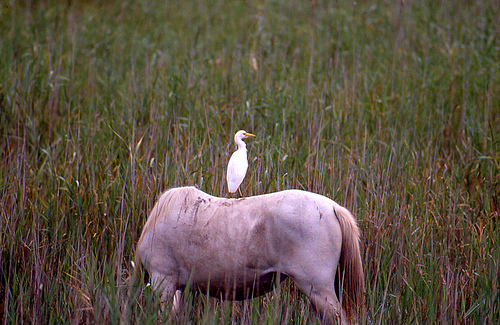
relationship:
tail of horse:
[332, 200, 374, 318] [71, 120, 417, 323]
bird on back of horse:
[225, 129, 257, 197] [118, 186, 367, 323]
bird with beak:
[225, 129, 257, 197] [244, 129, 256, 136]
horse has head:
[131, 185, 368, 324] [103, 248, 146, 321]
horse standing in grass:
[131, 185, 368, 324] [1, 0, 498, 322]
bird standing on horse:
[225, 129, 257, 197] [118, 186, 367, 323]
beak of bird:
[242, 132, 256, 137] [225, 127, 253, 197]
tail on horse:
[332, 200, 374, 318] [108, 185, 435, 321]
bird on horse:
[225, 129, 257, 197] [118, 186, 367, 323]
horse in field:
[118, 186, 367, 323] [3, 5, 498, 320]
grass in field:
[2, 2, 499, 128] [3, 5, 498, 320]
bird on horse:
[225, 129, 257, 197] [138, 178, 363, 323]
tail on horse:
[332, 200, 374, 318] [118, 186, 367, 323]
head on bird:
[235, 131, 252, 138] [225, 127, 253, 197]